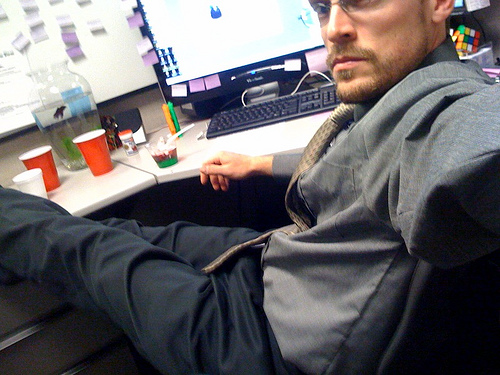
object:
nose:
[322, 7, 354, 43]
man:
[0, 0, 500, 374]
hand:
[197, 151, 254, 191]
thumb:
[201, 163, 234, 179]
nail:
[197, 165, 209, 175]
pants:
[0, 193, 281, 370]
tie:
[200, 106, 364, 273]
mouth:
[326, 50, 368, 73]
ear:
[427, 0, 451, 25]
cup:
[67, 128, 115, 175]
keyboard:
[204, 83, 341, 140]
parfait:
[141, 134, 178, 169]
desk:
[105, 94, 333, 186]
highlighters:
[156, 103, 184, 141]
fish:
[50, 101, 70, 123]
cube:
[450, 26, 481, 55]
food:
[140, 125, 176, 168]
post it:
[203, 74, 223, 91]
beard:
[333, 82, 378, 105]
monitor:
[147, 4, 325, 87]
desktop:
[142, 1, 348, 139]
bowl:
[27, 55, 101, 171]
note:
[171, 80, 187, 99]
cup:
[8, 168, 48, 198]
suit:
[260, 36, 500, 370]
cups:
[16, 143, 61, 191]